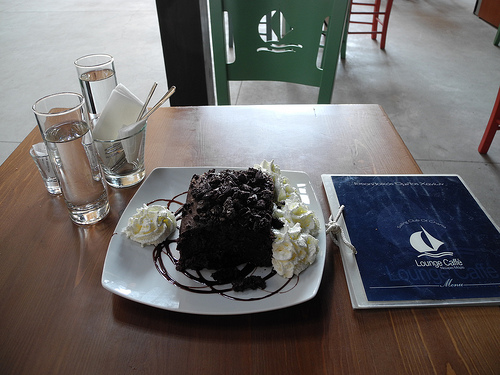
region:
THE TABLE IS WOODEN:
[313, 334, 333, 361]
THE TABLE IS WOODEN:
[309, 338, 324, 360]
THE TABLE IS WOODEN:
[309, 326, 319, 348]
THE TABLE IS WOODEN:
[274, 348, 290, 361]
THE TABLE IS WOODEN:
[270, 342, 284, 363]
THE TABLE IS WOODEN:
[294, 344, 304, 366]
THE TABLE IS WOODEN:
[303, 329, 315, 359]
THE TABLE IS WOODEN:
[302, 332, 324, 341]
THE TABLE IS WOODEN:
[295, 326, 312, 355]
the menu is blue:
[340, 152, 497, 357]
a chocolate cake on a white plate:
[153, 165, 320, 305]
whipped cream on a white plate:
[118, 187, 173, 249]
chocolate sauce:
[148, 245, 193, 291]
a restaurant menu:
[316, 166, 497, 322]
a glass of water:
[36, 103, 109, 218]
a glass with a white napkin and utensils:
[86, 82, 166, 164]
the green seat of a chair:
[211, 4, 350, 100]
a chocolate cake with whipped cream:
[118, 155, 328, 323]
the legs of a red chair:
[348, 0, 393, 52]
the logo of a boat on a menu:
[395, 221, 470, 278]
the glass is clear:
[77, 183, 95, 186]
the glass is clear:
[90, 207, 93, 214]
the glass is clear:
[68, 194, 104, 233]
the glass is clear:
[81, 180, 108, 222]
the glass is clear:
[97, 208, 107, 223]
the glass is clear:
[74, 205, 98, 225]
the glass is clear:
[69, 203, 96, 216]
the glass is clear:
[56, 180, 88, 203]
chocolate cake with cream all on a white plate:
[99, 156, 328, 319]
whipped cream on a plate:
[125, 200, 177, 253]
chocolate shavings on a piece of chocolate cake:
[191, 168, 276, 219]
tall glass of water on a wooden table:
[31, 90, 113, 234]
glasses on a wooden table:
[23, 47, 158, 225]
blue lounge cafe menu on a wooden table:
[328, 170, 497, 311]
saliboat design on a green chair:
[251, 6, 309, 57]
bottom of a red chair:
[345, 1, 402, 54]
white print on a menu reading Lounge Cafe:
[412, 258, 478, 273]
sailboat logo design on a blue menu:
[407, 224, 459, 258]